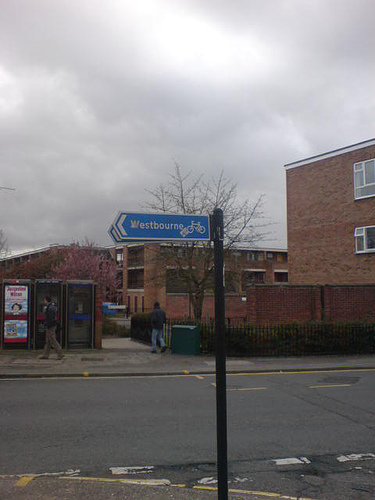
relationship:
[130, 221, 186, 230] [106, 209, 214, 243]
letter on blue sign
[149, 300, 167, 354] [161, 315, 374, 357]
guy walking along fence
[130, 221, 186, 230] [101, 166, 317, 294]
letter on sign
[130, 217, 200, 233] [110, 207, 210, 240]
letter on sign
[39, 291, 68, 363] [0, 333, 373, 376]
guy walking on sidewalk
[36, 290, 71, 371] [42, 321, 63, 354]
guy wearing pants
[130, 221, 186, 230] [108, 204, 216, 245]
letter on sign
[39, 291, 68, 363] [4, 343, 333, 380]
guy walking on sidewalk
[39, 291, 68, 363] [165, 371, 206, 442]
guy walking on side walk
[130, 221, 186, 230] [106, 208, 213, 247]
letter on sign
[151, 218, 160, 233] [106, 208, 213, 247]
letter "b" on sign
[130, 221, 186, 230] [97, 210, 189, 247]
letter on sign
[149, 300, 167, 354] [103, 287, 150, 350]
guy walking towards entrance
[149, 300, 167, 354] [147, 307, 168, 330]
guy keeping hands in jacket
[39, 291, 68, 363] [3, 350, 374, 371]
guy walking on sidewalk